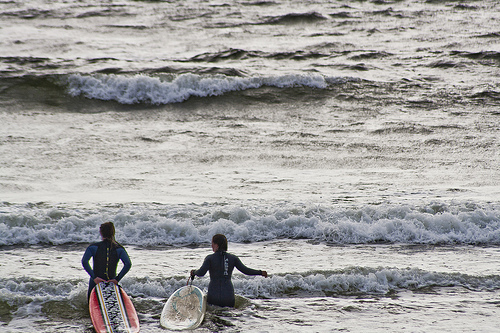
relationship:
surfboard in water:
[87, 283, 145, 332] [1, 1, 498, 328]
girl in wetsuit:
[81, 220, 132, 295] [80, 240, 132, 298]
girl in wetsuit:
[187, 232, 268, 309] [200, 250, 255, 299]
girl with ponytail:
[81, 220, 132, 295] [108, 222, 118, 244]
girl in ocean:
[81, 220, 132, 295] [5, 4, 495, 326]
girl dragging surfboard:
[187, 232, 268, 309] [157, 283, 207, 328]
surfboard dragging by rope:
[157, 283, 207, 328] [187, 272, 194, 288]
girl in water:
[81, 220, 132, 306] [1, 1, 498, 328]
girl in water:
[187, 232, 273, 309] [1, 1, 498, 328]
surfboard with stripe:
[87, 283, 139, 331] [98, 280, 129, 330]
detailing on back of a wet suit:
[102, 243, 111, 280] [80, 240, 132, 301]